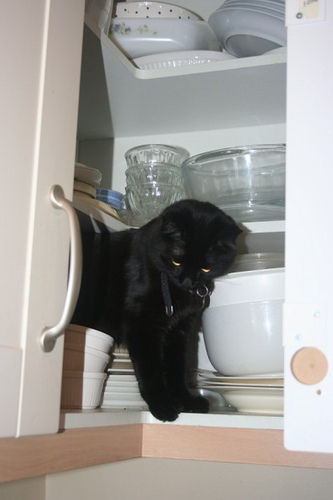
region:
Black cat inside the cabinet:
[75, 199, 257, 404]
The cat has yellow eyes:
[169, 254, 220, 290]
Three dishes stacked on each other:
[61, 315, 109, 413]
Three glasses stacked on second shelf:
[106, 138, 215, 217]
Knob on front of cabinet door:
[274, 339, 331, 400]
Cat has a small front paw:
[139, 395, 184, 429]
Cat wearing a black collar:
[145, 265, 185, 319]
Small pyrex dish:
[105, 15, 217, 54]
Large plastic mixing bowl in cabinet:
[193, 254, 318, 389]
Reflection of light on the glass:
[213, 158, 269, 194]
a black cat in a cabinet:
[70, 190, 253, 430]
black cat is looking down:
[78, 176, 254, 431]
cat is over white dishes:
[71, 188, 256, 423]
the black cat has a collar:
[150, 277, 215, 324]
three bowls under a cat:
[69, 321, 112, 410]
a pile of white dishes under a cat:
[103, 333, 149, 422]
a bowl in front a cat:
[197, 284, 285, 378]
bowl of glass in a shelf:
[116, 147, 192, 226]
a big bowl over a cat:
[184, 147, 289, 222]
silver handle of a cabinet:
[43, 175, 89, 356]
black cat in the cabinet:
[64, 192, 249, 425]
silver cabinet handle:
[38, 185, 86, 356]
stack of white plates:
[209, 0, 287, 58]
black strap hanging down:
[159, 271, 179, 314]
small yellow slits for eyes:
[169, 255, 218, 273]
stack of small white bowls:
[62, 319, 112, 411]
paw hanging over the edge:
[152, 401, 180, 424]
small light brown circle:
[288, 345, 328, 390]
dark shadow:
[61, 328, 88, 405]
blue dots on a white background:
[116, 5, 192, 21]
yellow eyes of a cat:
[157, 251, 218, 278]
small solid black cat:
[59, 180, 252, 430]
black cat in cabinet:
[45, 111, 297, 441]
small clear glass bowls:
[116, 132, 187, 202]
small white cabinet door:
[1, 27, 84, 443]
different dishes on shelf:
[101, 0, 300, 84]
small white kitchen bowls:
[58, 319, 118, 418]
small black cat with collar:
[144, 190, 248, 329]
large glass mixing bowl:
[178, 132, 297, 218]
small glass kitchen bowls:
[91, 181, 127, 211]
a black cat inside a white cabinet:
[58, 189, 255, 430]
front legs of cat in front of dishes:
[114, 331, 213, 428]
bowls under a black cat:
[70, 326, 115, 423]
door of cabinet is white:
[6, 13, 94, 437]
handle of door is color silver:
[37, 180, 90, 370]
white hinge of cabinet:
[266, 294, 327, 357]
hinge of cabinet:
[274, 295, 328, 352]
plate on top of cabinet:
[202, 0, 285, 60]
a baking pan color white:
[126, 47, 241, 72]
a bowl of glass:
[177, 143, 284, 206]